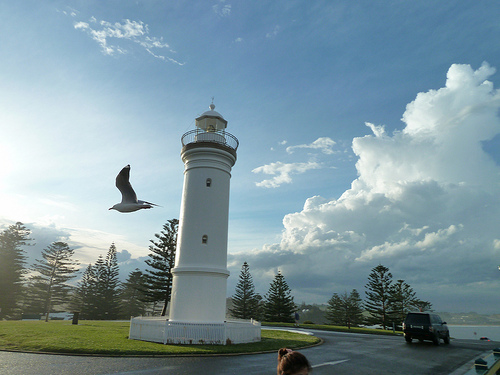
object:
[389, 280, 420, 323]
tree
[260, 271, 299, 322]
tree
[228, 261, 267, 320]
tree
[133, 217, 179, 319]
tree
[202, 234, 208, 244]
lighthouse window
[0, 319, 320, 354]
grass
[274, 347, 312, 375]
head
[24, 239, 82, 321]
tree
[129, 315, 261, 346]
fence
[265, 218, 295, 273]
floor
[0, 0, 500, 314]
sky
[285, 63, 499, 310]
clouds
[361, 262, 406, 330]
tree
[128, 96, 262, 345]
building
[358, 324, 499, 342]
lake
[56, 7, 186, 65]
clouds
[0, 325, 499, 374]
parking lot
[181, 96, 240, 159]
top section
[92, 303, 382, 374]
round about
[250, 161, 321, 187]
cloud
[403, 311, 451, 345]
car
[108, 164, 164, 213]
bird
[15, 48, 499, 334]
day